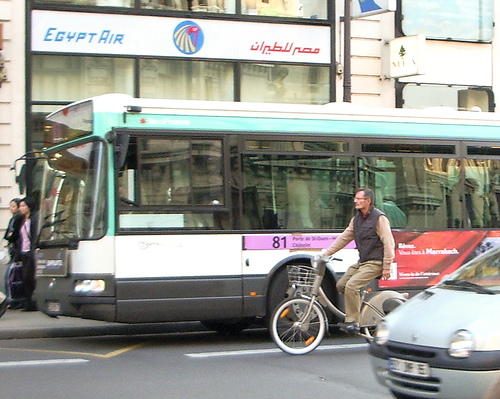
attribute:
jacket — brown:
[353, 213, 388, 261]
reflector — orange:
[281, 309, 291, 319]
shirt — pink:
[21, 221, 30, 253]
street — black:
[2, 330, 379, 398]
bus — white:
[12, 94, 499, 336]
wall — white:
[343, 15, 385, 108]